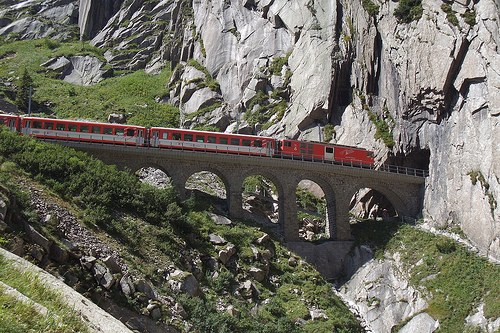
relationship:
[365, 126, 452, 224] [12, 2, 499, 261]
tunnel in mountain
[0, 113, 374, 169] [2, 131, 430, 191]
train rides on tracks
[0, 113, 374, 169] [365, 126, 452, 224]
train enters tunnel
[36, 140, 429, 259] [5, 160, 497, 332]
bridge over gully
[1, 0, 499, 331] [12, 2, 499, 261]
grass grows on mountain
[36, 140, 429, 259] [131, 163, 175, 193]
bridge has arch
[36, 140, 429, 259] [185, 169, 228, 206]
bridge has arch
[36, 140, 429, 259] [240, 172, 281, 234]
bridge has arch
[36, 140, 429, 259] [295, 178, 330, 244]
bridge has arch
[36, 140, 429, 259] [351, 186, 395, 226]
bridge has arch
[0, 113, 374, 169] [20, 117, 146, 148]
train has car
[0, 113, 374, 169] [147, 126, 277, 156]
train has car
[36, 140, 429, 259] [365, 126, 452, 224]
bridge enters tunnel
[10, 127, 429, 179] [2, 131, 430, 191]
railing alongside tracks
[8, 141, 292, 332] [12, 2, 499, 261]
bushes on mountain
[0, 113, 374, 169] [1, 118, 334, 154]
train has windows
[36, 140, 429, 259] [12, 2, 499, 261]
bridge enters mountain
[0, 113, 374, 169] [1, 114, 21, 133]
train has car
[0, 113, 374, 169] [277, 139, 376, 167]
train has car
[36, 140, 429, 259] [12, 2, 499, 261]
bridge going through mountain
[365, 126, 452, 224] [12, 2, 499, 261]
tunnel going through mountain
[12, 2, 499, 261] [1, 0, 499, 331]
mountain has grass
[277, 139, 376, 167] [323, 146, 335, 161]
car has door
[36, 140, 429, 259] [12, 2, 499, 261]
bridge in mountain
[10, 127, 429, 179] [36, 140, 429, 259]
railing on bridge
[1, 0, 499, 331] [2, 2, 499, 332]
grass on top of rocks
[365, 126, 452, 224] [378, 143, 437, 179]
tunnel has entrance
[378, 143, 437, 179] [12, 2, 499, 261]
entrance in mountain